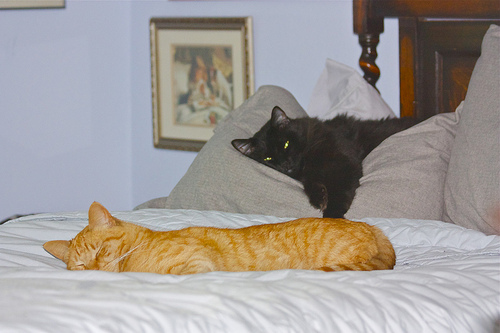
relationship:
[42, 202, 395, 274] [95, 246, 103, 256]
cat has eye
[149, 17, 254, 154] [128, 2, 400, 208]
picture hanging on wall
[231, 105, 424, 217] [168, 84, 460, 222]
cat laying on pillow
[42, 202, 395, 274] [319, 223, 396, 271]
cat has tail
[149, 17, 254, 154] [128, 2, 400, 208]
picture on wall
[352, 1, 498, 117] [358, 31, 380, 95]
headboard has spinal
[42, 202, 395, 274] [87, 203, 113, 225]
cat has ear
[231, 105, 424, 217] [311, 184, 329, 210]
cat has paw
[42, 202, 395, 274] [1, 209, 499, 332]
cat on top of comforter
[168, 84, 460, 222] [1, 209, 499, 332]
pillow on top of comforter